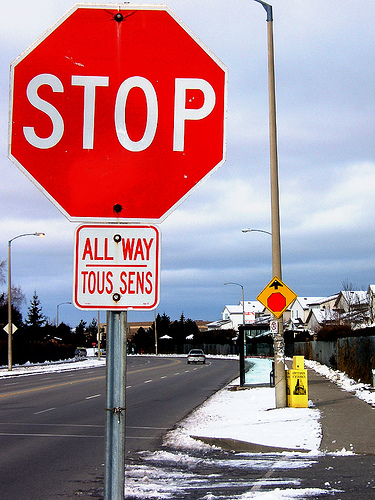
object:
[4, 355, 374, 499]
road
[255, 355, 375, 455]
sidewalk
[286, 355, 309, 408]
dispenser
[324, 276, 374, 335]
tree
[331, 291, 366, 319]
house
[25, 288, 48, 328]
tree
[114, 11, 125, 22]
screw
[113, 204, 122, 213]
screw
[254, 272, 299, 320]
traffic sign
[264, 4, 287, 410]
pole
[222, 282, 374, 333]
white snow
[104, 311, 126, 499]
pole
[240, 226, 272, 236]
light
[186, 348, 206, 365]
car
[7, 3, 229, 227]
stop sign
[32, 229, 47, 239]
steet light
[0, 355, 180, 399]
yellow lines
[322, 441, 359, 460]
snow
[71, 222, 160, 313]
sign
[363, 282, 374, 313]
shelter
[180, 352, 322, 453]
snow